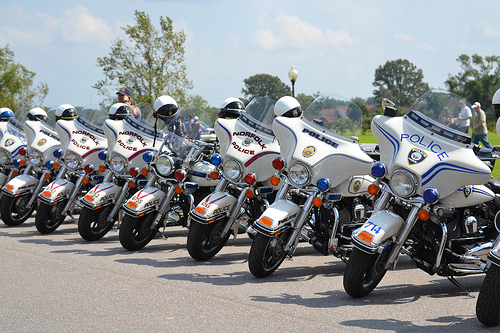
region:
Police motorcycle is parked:
[345, 62, 481, 312]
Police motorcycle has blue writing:
[376, 116, 483, 174]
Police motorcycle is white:
[336, 110, 482, 268]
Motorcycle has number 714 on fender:
[353, 200, 402, 270]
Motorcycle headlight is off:
[386, 165, 419, 215]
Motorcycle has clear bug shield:
[376, 72, 482, 171]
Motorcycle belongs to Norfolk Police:
[191, 95, 279, 270]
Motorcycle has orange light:
[341, 206, 396, 302]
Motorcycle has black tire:
[332, 230, 405, 309]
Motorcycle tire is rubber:
[338, 216, 395, 302]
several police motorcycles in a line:
[1, 70, 481, 316]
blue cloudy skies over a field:
[188, 7, 421, 84]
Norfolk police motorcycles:
[55, 93, 275, 218]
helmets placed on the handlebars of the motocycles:
[1, 86, 336, 132]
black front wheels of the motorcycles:
[2, 181, 492, 323]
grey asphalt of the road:
[18, 242, 312, 323]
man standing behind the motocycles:
[96, 73, 143, 121]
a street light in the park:
[281, 53, 312, 95]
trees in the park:
[1, 18, 198, 95]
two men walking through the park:
[441, 94, 496, 150]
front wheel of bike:
[337, 239, 400, 304]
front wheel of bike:
[234, 220, 300, 285]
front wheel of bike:
[164, 201, 250, 280]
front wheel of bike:
[109, 197, 170, 271]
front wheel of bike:
[64, 178, 126, 240]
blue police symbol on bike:
[382, 125, 464, 177]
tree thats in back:
[359, 56, 446, 107]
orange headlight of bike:
[250, 200, 282, 242]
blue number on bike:
[360, 208, 392, 238]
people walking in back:
[440, 86, 495, 138]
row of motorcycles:
[3, 93, 498, 332]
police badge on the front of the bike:
[403, 142, 428, 169]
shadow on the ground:
[340, 318, 490, 332]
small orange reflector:
[364, 179, 381, 199]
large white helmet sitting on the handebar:
[266, 91, 303, 123]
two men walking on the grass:
[446, 88, 498, 153]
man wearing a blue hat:
[108, 82, 145, 126]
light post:
[285, 65, 300, 99]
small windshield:
[401, 86, 473, 137]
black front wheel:
[338, 216, 403, 303]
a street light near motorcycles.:
[278, 62, 309, 108]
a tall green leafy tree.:
[96, 11, 203, 141]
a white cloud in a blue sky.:
[246, 8, 329, 58]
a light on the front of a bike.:
[359, 217, 376, 247]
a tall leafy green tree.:
[0, 36, 67, 116]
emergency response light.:
[268, 140, 340, 208]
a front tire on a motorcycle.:
[326, 251, 388, 308]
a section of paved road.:
[1, 205, 498, 330]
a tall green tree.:
[213, 64, 298, 130]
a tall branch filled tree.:
[0, 43, 55, 115]